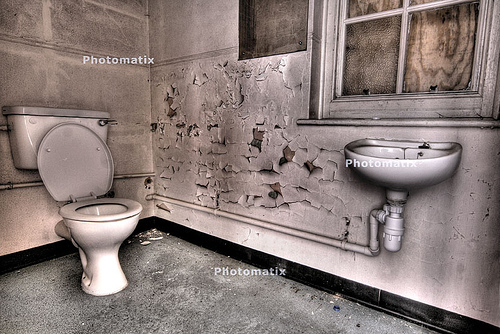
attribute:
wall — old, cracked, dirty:
[150, 1, 499, 329]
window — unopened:
[323, 1, 495, 117]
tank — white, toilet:
[3, 106, 111, 169]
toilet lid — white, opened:
[37, 121, 115, 203]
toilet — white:
[36, 120, 142, 296]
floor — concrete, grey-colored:
[1, 226, 439, 333]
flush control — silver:
[96, 119, 116, 126]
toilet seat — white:
[58, 196, 143, 222]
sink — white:
[343, 137, 462, 202]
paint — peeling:
[156, 60, 345, 216]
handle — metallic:
[99, 119, 117, 127]